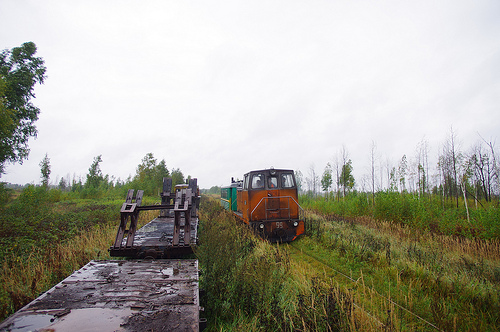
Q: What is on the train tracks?
A: A train.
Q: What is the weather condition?
A: Cloudy.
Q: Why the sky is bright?
A: It's noon.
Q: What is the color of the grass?
A: Green.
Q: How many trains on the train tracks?
A: One.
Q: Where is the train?
A: On the train tracks.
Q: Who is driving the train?
A: A person.